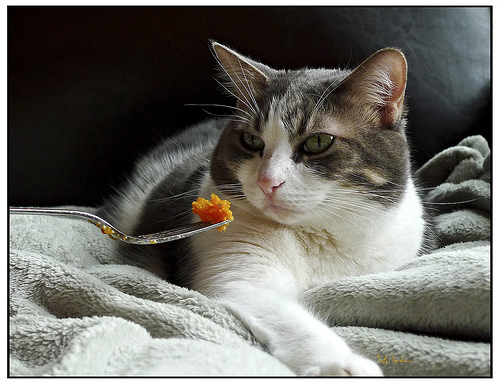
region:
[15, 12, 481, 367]
a cat being fed from a fork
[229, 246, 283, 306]
soft white fur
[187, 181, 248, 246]
a fork with some orange food on it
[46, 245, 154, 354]
a soft grey blanket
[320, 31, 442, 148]
a cat's ear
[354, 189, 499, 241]
long fine whiskers on a cat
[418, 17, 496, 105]
a black leather couch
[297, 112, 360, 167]
a green cat's eye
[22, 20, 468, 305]
a very spoiled pet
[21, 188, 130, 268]
the handle of a fork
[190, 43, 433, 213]
a cat's furry head.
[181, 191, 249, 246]
orange food on a fork.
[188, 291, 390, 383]
a right cat's arm.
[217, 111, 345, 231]
a cats furry face.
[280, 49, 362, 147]
whiskers on a cat.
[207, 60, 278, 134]
whiskers on a cat's face.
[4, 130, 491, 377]
a blanket under a cat.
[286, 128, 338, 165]
a cat's left eye.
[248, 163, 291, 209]
a pink cat nose.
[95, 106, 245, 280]
the body of a cat.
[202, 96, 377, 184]
Cat's eyes are green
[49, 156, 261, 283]
Food on the fork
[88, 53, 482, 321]
Cat is black and white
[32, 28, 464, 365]
Blanket is grey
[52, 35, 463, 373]
Cat is lying on the blanket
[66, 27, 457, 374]
Sun is reflecting on the cat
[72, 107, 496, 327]
Cat is being fed food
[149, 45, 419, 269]
Cat is looking at the food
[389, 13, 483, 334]
Nothing is on the blanket there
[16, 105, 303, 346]
Someone is holding the fork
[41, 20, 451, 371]
cat laying on some blankets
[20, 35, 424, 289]
cat laying on blanket with food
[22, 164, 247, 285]
fork with food on the end of it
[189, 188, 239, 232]
or food on tip of fork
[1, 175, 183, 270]
silver fork in the air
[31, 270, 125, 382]
grey fuzzy blanket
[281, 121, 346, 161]
green and black cat eye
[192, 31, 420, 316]
white and brown cat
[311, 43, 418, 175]
furry cat ear with orange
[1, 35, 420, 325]
cat starring at food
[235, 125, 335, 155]
green eyes of a house cat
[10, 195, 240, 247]
silver metal fork with cat food on it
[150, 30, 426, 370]
brown and white furred cat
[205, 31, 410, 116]
ears of a furry cat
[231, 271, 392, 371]
furry white cat paw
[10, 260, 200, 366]
fluffy grey blanket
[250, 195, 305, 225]
closed mouth of a furry cat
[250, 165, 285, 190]
pink nose of a furry cat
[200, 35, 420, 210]
head of a furry cat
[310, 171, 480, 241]
long white cat whiskers